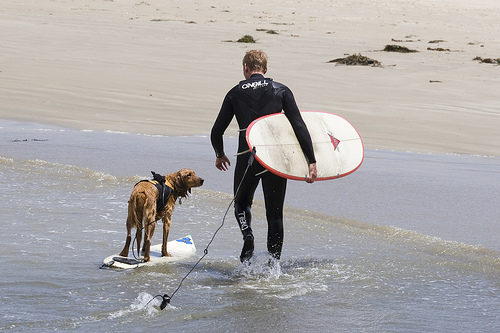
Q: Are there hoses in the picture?
A: No, there are no hoses.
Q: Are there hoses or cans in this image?
A: No, there are no hoses or cans.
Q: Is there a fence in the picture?
A: No, there are no fences.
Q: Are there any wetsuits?
A: Yes, there is a wetsuit.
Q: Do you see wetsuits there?
A: Yes, there is a wetsuit.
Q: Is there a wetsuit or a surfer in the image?
A: Yes, there is a wetsuit.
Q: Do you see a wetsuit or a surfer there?
A: Yes, there is a wetsuit.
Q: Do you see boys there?
A: No, there are no boys.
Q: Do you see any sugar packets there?
A: No, there are no sugar packets.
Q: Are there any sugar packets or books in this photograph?
A: No, there are no sugar packets or books.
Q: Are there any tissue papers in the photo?
A: No, there are no tissue papers.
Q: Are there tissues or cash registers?
A: No, there are no tissues or cash registers.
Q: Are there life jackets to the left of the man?
A: Yes, there is a life jacket to the left of the man.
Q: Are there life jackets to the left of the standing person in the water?
A: Yes, there is a life jacket to the left of the man.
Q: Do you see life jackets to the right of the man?
A: No, the life jacket is to the left of the man.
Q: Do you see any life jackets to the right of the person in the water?
A: No, the life jacket is to the left of the man.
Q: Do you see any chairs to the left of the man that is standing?
A: No, there is a life jacket to the left of the man.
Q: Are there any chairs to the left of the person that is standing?
A: No, there is a life jacket to the left of the man.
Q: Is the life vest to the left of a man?
A: Yes, the life vest is to the left of a man.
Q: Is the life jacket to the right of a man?
A: No, the life jacket is to the left of a man.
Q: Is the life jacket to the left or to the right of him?
A: The life jacket is to the left of the man.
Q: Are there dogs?
A: Yes, there is a dog.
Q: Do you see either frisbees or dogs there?
A: Yes, there is a dog.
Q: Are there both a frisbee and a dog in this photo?
A: No, there is a dog but no frisbees.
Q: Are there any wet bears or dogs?
A: Yes, there is a wet dog.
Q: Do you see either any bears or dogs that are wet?
A: Yes, the dog is wet.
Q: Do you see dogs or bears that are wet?
A: Yes, the dog is wet.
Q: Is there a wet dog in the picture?
A: Yes, there is a wet dog.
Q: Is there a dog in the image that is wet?
A: Yes, there is a dog that is wet.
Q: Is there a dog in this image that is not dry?
A: Yes, there is a wet dog.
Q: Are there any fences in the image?
A: No, there are no fences.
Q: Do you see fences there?
A: No, there are no fences.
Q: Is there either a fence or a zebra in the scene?
A: No, there are no fences or zebras.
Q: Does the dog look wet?
A: Yes, the dog is wet.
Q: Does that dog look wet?
A: Yes, the dog is wet.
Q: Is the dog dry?
A: No, the dog is wet.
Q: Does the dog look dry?
A: No, the dog is wet.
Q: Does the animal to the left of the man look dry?
A: No, the dog is wet.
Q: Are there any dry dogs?
A: No, there is a dog but it is wet.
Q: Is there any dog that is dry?
A: No, there is a dog but it is wet.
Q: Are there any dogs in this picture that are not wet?
A: No, there is a dog but it is wet.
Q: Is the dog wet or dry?
A: The dog is wet.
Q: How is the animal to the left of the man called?
A: The animal is a dog.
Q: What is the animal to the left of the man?
A: The animal is a dog.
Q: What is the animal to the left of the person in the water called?
A: The animal is a dog.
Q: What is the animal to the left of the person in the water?
A: The animal is a dog.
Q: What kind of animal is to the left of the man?
A: The animal is a dog.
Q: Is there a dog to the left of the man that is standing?
A: Yes, there is a dog to the left of the man.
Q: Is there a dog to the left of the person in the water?
A: Yes, there is a dog to the left of the man.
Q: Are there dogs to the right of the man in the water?
A: No, the dog is to the left of the man.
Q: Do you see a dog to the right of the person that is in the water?
A: No, the dog is to the left of the man.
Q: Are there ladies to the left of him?
A: No, there is a dog to the left of the man.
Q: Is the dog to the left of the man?
A: Yes, the dog is to the left of the man.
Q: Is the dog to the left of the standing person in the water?
A: Yes, the dog is to the left of the man.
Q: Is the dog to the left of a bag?
A: No, the dog is to the left of the man.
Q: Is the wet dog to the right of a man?
A: No, the dog is to the left of a man.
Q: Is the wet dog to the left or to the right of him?
A: The dog is to the left of the man.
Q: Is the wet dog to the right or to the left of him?
A: The dog is to the left of the man.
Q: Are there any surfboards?
A: Yes, there is a surfboard.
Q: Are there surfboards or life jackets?
A: Yes, there is a surfboard.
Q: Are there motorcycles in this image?
A: No, there are no motorcycles.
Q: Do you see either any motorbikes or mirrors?
A: No, there are no motorbikes or mirrors.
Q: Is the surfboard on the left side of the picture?
A: Yes, the surfboard is on the left of the image.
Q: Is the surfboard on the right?
A: No, the surfboard is on the left of the image.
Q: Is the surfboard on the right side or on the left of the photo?
A: The surfboard is on the left of the image.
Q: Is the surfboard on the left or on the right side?
A: The surfboard is on the left of the image.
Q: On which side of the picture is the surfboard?
A: The surfboard is on the left of the image.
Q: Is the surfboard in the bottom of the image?
A: Yes, the surfboard is in the bottom of the image.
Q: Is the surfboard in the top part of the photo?
A: No, the surfboard is in the bottom of the image.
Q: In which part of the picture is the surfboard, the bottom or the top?
A: The surfboard is in the bottom of the image.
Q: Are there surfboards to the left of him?
A: Yes, there is a surfboard to the left of the man.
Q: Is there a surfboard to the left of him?
A: Yes, there is a surfboard to the left of the man.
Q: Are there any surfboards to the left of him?
A: Yes, there is a surfboard to the left of the man.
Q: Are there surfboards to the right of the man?
A: No, the surfboard is to the left of the man.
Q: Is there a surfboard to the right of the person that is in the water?
A: No, the surfboard is to the left of the man.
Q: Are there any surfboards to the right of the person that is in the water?
A: No, the surfboard is to the left of the man.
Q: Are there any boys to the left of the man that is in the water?
A: No, there is a surfboard to the left of the man.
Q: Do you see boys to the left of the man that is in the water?
A: No, there is a surfboard to the left of the man.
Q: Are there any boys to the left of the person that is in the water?
A: No, there is a surfboard to the left of the man.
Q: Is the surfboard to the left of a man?
A: Yes, the surfboard is to the left of a man.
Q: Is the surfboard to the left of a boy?
A: No, the surfboard is to the left of a man.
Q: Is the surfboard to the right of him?
A: No, the surfboard is to the left of the man.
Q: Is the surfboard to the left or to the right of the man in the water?
A: The surfboard is to the left of the man.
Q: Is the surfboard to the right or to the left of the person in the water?
A: The surfboard is to the left of the man.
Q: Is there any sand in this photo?
A: Yes, there is sand.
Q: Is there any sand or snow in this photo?
A: Yes, there is sand.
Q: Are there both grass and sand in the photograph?
A: No, there is sand but no grass.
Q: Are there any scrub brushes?
A: No, there are no scrub brushes.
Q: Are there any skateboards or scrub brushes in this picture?
A: No, there are no scrub brushes or skateboards.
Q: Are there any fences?
A: No, there are no fences.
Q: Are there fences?
A: No, there are no fences.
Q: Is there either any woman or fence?
A: No, there are no fences or women.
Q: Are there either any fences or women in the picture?
A: No, there are no fences or women.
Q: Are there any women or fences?
A: No, there are no fences or women.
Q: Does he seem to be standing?
A: Yes, the man is standing.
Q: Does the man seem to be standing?
A: Yes, the man is standing.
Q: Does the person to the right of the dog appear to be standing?
A: Yes, the man is standing.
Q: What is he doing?
A: The man is standing.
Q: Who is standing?
A: The man is standing.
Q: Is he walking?
A: No, the man is standing.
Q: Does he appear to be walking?
A: No, the man is standing.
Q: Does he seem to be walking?
A: No, the man is standing.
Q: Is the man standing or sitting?
A: The man is standing.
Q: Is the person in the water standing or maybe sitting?
A: The man is standing.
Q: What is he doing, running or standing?
A: The man is standing.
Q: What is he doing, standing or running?
A: The man is standing.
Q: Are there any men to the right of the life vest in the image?
A: Yes, there is a man to the right of the life vest.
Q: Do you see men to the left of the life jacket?
A: No, the man is to the right of the life jacket.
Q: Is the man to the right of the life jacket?
A: Yes, the man is to the right of the life jacket.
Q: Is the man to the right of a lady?
A: No, the man is to the right of the life jacket.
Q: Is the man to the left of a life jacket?
A: No, the man is to the right of a life jacket.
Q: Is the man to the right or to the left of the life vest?
A: The man is to the right of the life vest.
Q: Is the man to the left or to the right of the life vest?
A: The man is to the right of the life vest.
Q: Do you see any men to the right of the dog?
A: Yes, there is a man to the right of the dog.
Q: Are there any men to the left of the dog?
A: No, the man is to the right of the dog.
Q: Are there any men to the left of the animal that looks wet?
A: No, the man is to the right of the dog.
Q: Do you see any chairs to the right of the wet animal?
A: No, there is a man to the right of the dog.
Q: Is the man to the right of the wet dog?
A: Yes, the man is to the right of the dog.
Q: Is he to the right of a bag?
A: No, the man is to the right of the dog.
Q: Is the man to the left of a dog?
A: No, the man is to the right of a dog.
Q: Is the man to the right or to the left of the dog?
A: The man is to the right of the dog.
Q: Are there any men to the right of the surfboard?
A: Yes, there is a man to the right of the surfboard.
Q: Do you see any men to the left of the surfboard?
A: No, the man is to the right of the surfboard.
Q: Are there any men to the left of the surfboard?
A: No, the man is to the right of the surfboard.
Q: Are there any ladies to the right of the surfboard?
A: No, there is a man to the right of the surfboard.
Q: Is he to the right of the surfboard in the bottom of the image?
A: Yes, the man is to the right of the surf board.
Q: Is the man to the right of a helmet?
A: No, the man is to the right of the surf board.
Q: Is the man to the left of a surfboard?
A: No, the man is to the right of a surfboard.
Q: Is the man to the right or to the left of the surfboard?
A: The man is to the right of the surfboard.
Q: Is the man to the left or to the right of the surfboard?
A: The man is to the right of the surfboard.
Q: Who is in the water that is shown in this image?
A: The man is in the water.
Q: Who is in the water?
A: The man is in the water.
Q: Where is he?
A: The man is in the water.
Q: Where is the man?
A: The man is in the water.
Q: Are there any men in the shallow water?
A: Yes, there is a man in the water.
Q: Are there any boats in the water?
A: No, there is a man in the water.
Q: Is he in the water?
A: Yes, the man is in the water.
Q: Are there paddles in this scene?
A: No, there are no paddles.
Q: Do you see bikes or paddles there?
A: No, there are no paddles or bikes.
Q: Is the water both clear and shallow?
A: Yes, the water is clear and shallow.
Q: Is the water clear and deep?
A: No, the water is clear but shallow.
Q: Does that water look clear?
A: Yes, the water is clear.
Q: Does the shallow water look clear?
A: Yes, the water is clear.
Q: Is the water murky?
A: No, the water is clear.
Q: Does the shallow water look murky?
A: No, the water is clear.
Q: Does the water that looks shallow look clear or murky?
A: The water is clear.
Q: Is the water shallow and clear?
A: Yes, the water is shallow and clear.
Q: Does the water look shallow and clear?
A: Yes, the water is shallow and clear.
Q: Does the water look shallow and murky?
A: No, the water is shallow but clear.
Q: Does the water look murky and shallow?
A: No, the water is shallow but clear.